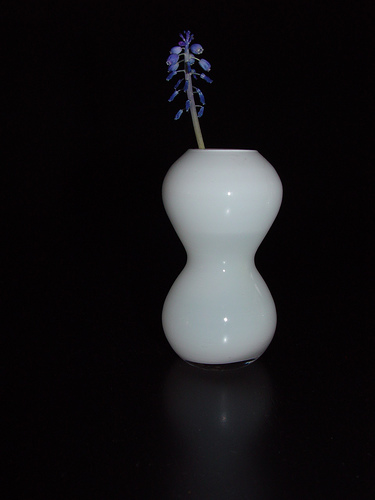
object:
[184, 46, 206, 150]
stem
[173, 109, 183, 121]
flowers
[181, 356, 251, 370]
vase bottom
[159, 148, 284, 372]
vase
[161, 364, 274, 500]
reflection